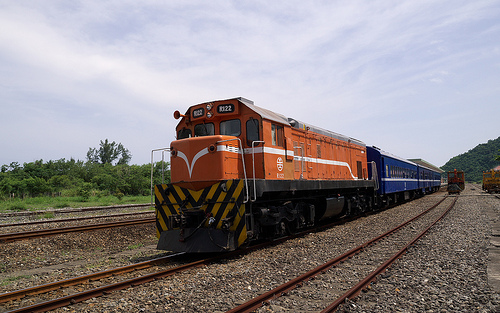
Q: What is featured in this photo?
A: A train.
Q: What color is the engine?
A: Orange.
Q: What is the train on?
A: Rails.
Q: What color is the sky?
A: Blue.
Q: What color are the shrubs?
A: Green.